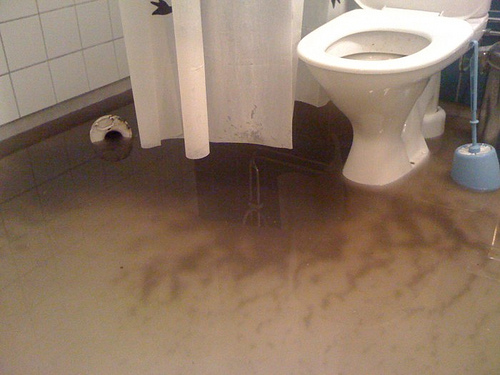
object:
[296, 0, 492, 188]
white toilet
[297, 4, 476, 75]
seat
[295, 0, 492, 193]
toilet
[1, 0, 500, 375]
bathroom